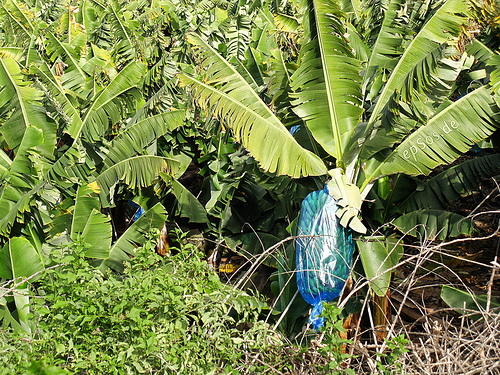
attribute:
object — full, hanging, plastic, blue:
[294, 187, 355, 332]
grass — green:
[0, 341, 156, 375]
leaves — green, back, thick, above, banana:
[0, 238, 196, 327]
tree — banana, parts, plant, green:
[175, 2, 497, 234]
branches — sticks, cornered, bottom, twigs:
[386, 305, 500, 373]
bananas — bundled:
[297, 192, 355, 303]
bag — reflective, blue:
[294, 187, 354, 334]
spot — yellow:
[219, 255, 245, 276]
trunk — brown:
[371, 296, 394, 345]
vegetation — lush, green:
[1, 0, 499, 334]